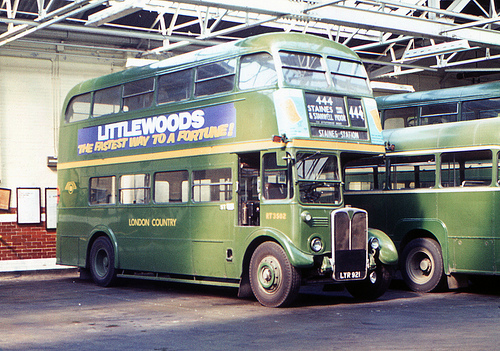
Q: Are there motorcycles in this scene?
A: No, there are no motorcycles.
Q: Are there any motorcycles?
A: No, there are no motorcycles.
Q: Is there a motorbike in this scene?
A: No, there are no motorcycles.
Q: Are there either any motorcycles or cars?
A: No, there are no motorcycles or cars.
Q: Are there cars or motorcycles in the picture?
A: No, there are no motorcycles or cars.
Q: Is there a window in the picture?
A: Yes, there is a window.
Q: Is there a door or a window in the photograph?
A: Yes, there is a window.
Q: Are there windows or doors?
A: Yes, there is a window.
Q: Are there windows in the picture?
A: Yes, there is a window.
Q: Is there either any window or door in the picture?
A: Yes, there is a window.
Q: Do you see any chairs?
A: No, there are no chairs.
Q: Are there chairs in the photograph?
A: No, there are no chairs.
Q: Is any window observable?
A: Yes, there is a window.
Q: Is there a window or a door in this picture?
A: Yes, there is a window.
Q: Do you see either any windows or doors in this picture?
A: Yes, there is a window.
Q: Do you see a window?
A: Yes, there is a window.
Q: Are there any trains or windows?
A: Yes, there is a window.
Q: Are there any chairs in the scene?
A: No, there are no chairs.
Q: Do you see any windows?
A: Yes, there is a window.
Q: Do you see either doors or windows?
A: Yes, there is a window.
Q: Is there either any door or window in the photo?
A: Yes, there is a window.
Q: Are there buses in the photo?
A: Yes, there is a bus.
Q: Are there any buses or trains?
A: Yes, there is a bus.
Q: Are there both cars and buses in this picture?
A: No, there is a bus but no cars.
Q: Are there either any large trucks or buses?
A: Yes, there is a large bus.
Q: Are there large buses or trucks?
A: Yes, there is a large bus.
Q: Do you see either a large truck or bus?
A: Yes, there is a large bus.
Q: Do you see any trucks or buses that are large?
A: Yes, the bus is large.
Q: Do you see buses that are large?
A: Yes, there is a large bus.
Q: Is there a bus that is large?
A: Yes, there is a bus that is large.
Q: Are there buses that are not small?
A: Yes, there is a large bus.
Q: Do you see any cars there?
A: No, there are no cars.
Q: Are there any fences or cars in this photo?
A: No, there are no cars or fences.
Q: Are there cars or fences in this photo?
A: No, there are no cars or fences.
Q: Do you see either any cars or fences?
A: No, there are no cars or fences.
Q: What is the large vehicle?
A: The vehicle is a bus.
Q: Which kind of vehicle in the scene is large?
A: The vehicle is a bus.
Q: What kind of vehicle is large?
A: The vehicle is a bus.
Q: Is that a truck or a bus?
A: That is a bus.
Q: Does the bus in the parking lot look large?
A: Yes, the bus is large.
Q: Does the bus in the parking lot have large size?
A: Yes, the bus is large.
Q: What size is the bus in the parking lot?
A: The bus is large.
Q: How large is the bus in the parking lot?
A: The bus is large.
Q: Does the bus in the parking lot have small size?
A: No, the bus is large.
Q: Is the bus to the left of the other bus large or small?
A: The bus is large.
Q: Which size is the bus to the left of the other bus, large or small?
A: The bus is large.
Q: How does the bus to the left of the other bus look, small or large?
A: The bus is large.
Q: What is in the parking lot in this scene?
A: The bus is in the parking lot.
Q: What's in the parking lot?
A: The bus is in the parking lot.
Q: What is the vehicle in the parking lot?
A: The vehicle is a bus.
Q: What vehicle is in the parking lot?
A: The vehicle is a bus.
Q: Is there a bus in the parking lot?
A: Yes, there is a bus in the parking lot.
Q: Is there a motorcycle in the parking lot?
A: No, there is a bus in the parking lot.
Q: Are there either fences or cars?
A: No, there are no cars or fences.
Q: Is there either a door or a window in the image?
A: Yes, there is a window.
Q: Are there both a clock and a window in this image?
A: No, there is a window but no clocks.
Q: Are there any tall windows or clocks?
A: Yes, there is a tall window.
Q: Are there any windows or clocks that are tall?
A: Yes, the window is tall.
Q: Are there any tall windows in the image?
A: Yes, there is a tall window.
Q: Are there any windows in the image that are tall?
A: Yes, there is a window that is tall.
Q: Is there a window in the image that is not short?
A: Yes, there is a tall window.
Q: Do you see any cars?
A: No, there are no cars.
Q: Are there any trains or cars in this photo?
A: No, there are no cars or trains.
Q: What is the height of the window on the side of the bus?
A: The window is tall.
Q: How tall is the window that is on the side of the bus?
A: The window is tall.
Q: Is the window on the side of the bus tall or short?
A: The window is tall.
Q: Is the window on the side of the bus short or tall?
A: The window is tall.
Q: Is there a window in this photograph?
A: Yes, there is a window.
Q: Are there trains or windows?
A: Yes, there is a window.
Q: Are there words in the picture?
A: Yes, there are words.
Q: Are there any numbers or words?
A: Yes, there are words.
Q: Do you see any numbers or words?
A: Yes, there are words.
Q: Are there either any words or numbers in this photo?
A: Yes, there are words.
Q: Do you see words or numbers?
A: Yes, there are words.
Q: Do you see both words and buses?
A: Yes, there are both words and a bus.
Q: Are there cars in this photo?
A: No, there are no cars.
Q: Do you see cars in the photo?
A: No, there are no cars.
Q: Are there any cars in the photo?
A: No, there are no cars.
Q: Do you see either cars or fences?
A: No, there are no cars or fences.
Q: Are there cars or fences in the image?
A: No, there are no cars or fences.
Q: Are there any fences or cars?
A: No, there are no cars or fences.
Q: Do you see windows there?
A: Yes, there is a window.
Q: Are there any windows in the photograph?
A: Yes, there is a window.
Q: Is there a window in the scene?
A: Yes, there is a window.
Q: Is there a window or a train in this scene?
A: Yes, there is a window.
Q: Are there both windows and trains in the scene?
A: No, there is a window but no trains.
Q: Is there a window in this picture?
A: Yes, there is a window.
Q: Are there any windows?
A: Yes, there is a window.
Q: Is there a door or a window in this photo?
A: Yes, there is a window.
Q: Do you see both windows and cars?
A: No, there is a window but no cars.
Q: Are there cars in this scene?
A: No, there are no cars.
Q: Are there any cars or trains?
A: No, there are no cars or trains.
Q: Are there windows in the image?
A: Yes, there is a window.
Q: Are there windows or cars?
A: Yes, there is a window.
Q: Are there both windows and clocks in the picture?
A: No, there is a window but no clocks.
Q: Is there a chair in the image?
A: No, there are no chairs.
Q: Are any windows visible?
A: Yes, there is a window.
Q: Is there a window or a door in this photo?
A: Yes, there is a window.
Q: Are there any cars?
A: No, there are no cars.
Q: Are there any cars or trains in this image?
A: No, there are no cars or trains.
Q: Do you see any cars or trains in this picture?
A: No, there are no cars or trains.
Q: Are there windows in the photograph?
A: Yes, there is a window.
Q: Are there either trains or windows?
A: Yes, there is a window.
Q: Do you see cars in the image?
A: No, there are no cars.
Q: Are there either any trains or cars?
A: No, there are no cars or trains.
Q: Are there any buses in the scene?
A: Yes, there is a bus.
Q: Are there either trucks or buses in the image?
A: Yes, there is a bus.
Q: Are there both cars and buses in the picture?
A: No, there is a bus but no cars.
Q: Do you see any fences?
A: No, there are no fences.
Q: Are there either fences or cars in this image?
A: No, there are no fences or cars.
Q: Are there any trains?
A: No, there are no trains.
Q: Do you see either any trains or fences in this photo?
A: No, there are no trains or fences.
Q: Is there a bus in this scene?
A: Yes, there is a bus.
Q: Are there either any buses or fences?
A: Yes, there is a bus.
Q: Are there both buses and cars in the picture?
A: No, there is a bus but no cars.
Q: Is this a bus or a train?
A: This is a bus.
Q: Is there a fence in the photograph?
A: No, there are no fences.